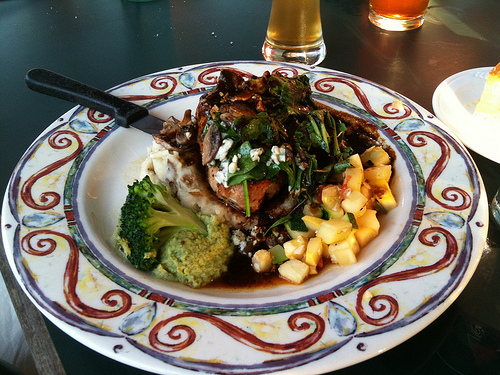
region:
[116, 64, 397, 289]
A dinner of steak, potatoes, and vegetables.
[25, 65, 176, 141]
A steak knife with a black handle.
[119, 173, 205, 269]
A single piece of broccoli.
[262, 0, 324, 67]
The bottom of a glass of light-colored beer.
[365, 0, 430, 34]
The bottom of a glass of amber-colored beer.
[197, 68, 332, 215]
A steak covered with mushrooms, spinach, and feta.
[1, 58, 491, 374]
A round plate with a brown and blue and green pattern.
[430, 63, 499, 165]
A white side dish.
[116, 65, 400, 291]
A meal with meat and vegetables.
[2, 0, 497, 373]
A shiny black tabletop.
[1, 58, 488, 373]
A white plate with food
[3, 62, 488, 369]
The white plate has designs on it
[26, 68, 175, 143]
A knife in the food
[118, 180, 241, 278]
broccoli on the plate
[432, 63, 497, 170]
Plain white plate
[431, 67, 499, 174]
The plain white plate has food on it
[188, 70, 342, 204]
Meat on the white plate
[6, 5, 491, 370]
A table that is holding the plates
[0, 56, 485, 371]
Designs on the plate are blue and red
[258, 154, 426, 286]
Chopped food on the plate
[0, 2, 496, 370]
This is a plate of food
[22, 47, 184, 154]
This is a knife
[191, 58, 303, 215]
This is a piece of food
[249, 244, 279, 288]
This is a piece of potatoe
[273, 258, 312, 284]
This is a piece of potatoe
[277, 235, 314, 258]
This is a piece of potatoe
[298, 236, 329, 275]
This is a piece of potatoe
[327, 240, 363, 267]
This is a piece of potatoe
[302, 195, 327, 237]
This is a piece of potatoe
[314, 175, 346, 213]
This is a piece of potatoe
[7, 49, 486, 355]
hearty meal with meat and veggies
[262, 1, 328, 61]
glass of beer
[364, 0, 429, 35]
glass of tea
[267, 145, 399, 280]
well seasoned bits of corn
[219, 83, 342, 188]
sauted spinach greens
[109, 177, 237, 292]
slightly overcooked broccoli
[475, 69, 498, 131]
square of corn bread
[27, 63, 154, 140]
black handled steak knife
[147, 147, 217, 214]
lumpy mash potatoes with skins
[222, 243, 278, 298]
brown sauce possibly made from drippings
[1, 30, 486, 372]
a healthy looking meal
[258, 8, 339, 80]
a glass of beer is setting there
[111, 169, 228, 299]
broccoli is on the plate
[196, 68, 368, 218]
the main dish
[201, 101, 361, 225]
a mixture of veggies & cheese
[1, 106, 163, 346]
the plate is multi colored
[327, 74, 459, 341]
the scrolls are red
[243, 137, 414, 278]
this is some kind of vegetable -- maybe squash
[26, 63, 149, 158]
the handle of the knife is black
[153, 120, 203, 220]
mashed potatoes or rice appears to be under the meat